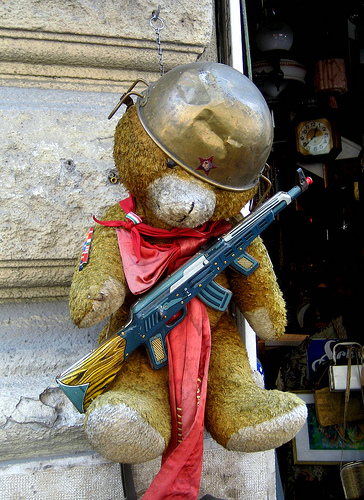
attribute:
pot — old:
[107, 62, 274, 210]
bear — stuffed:
[89, 93, 223, 253]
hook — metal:
[147, 5, 162, 23]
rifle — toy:
[51, 165, 318, 407]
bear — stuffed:
[64, 60, 296, 446]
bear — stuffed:
[71, 94, 253, 420]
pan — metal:
[117, 53, 283, 203]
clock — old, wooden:
[288, 108, 343, 165]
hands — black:
[292, 114, 333, 154]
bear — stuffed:
[63, 57, 307, 466]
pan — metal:
[109, 59, 274, 199]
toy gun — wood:
[53, 166, 312, 414]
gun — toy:
[46, 158, 326, 420]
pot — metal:
[105, 58, 288, 194]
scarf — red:
[117, 228, 229, 498]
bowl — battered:
[107, 60, 276, 193]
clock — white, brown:
[299, 118, 334, 154]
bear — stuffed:
[71, 101, 309, 450]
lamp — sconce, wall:
[251, 1, 297, 91]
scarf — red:
[89, 202, 239, 498]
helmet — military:
[97, 65, 272, 208]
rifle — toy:
[53, 60, 317, 463]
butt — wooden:
[67, 332, 130, 414]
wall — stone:
[28, 93, 85, 191]